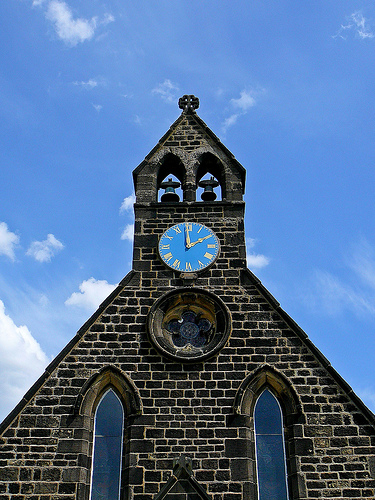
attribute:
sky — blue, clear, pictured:
[2, 3, 372, 427]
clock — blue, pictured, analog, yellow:
[157, 221, 221, 271]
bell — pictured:
[158, 175, 181, 203]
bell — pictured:
[196, 177, 223, 200]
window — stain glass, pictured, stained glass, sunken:
[85, 362, 127, 499]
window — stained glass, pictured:
[247, 387, 293, 499]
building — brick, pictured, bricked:
[6, 91, 372, 498]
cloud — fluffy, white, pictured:
[1, 220, 52, 426]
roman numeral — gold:
[196, 223, 206, 234]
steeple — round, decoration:
[177, 96, 199, 115]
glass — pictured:
[252, 393, 290, 497]